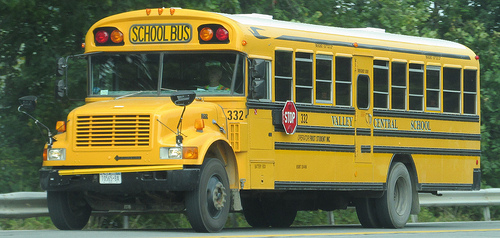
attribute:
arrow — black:
[112, 152, 142, 164]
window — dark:
[272, 47, 292, 105]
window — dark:
[293, 47, 313, 105]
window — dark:
[310, 49, 333, 106]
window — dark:
[333, 52, 350, 107]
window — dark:
[353, 73, 372, 109]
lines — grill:
[70, 109, 160, 153]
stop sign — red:
[280, 99, 299, 138]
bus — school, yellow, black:
[19, 35, 470, 230]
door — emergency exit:
[335, 44, 392, 176]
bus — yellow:
[40, 6, 487, 226]